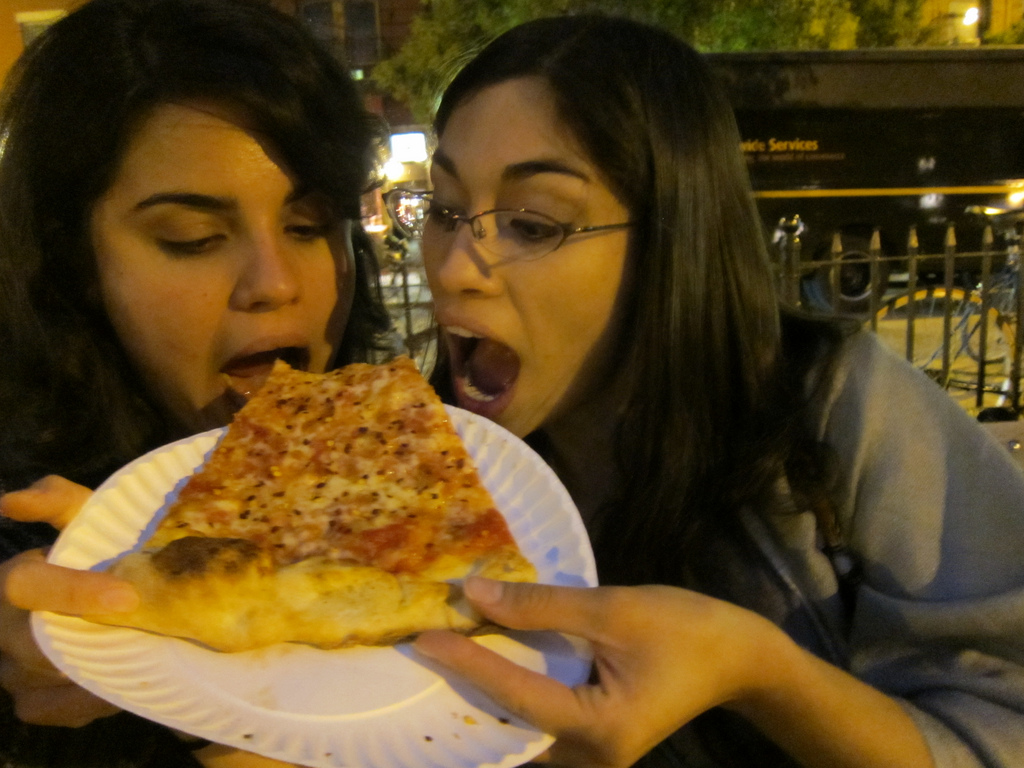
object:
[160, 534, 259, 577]
topping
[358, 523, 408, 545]
sauce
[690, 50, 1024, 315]
van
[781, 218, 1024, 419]
fence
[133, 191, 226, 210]
eyebrow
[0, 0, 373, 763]
girl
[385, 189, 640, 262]
glasses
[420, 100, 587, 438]
face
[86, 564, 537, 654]
crust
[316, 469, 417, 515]
cheese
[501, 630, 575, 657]
shadow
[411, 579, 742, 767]
hand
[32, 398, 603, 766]
plate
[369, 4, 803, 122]
trees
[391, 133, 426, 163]
light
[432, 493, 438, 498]
pepperoni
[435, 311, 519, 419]
mouth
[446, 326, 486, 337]
teeth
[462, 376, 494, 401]
teeth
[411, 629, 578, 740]
finger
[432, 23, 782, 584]
hair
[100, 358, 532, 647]
cheese pizza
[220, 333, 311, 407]
mouth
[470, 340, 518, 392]
tongue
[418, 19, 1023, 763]
girl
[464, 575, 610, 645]
left thumb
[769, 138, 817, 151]
services